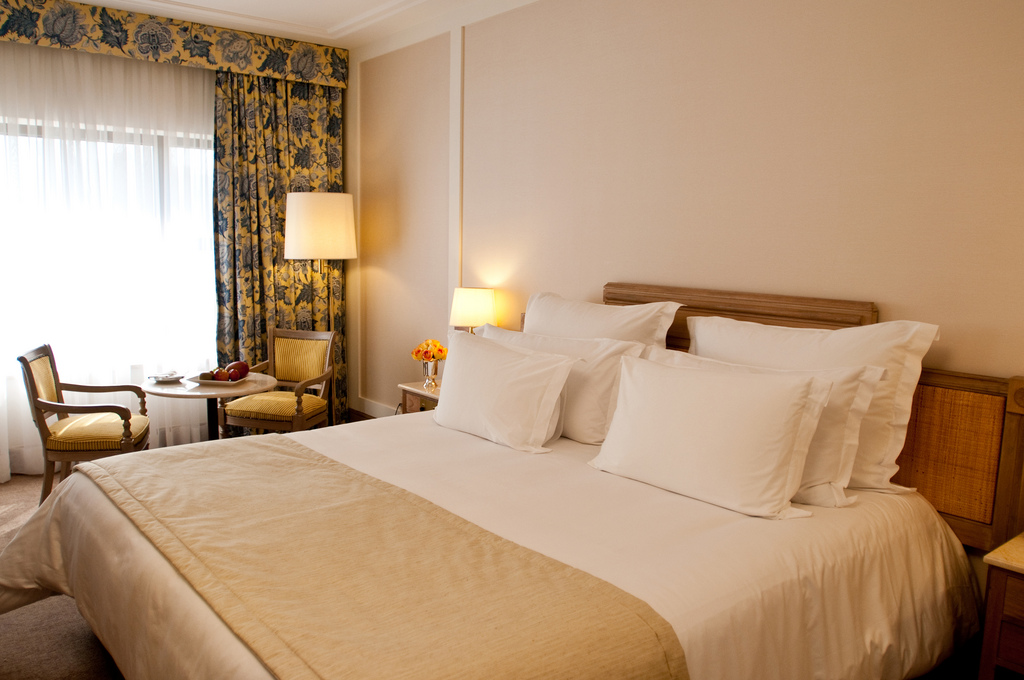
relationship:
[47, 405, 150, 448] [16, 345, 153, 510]
cushion on chair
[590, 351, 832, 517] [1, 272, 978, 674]
pillow on bed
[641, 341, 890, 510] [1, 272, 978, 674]
pillow on bed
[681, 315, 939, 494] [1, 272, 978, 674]
pillow on bed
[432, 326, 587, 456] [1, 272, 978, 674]
pillow on bed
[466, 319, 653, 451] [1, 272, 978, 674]
pillow on bed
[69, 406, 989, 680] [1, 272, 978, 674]
coverlet on bed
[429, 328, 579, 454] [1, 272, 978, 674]
pillow on bed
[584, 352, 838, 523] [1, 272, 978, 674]
pillow on bed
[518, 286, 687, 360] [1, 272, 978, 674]
pillow on bed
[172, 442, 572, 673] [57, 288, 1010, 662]
coverlet turned down on bed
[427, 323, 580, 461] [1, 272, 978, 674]
pillow on bed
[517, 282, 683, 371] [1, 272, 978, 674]
pillow on bed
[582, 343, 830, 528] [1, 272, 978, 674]
pillow on bed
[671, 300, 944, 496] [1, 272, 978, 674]
pillow on bed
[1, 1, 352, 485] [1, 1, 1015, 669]
window in hotel room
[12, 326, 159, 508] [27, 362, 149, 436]
chair with upholstery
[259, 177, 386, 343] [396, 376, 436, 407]
lamp on table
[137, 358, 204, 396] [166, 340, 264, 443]
objects on table